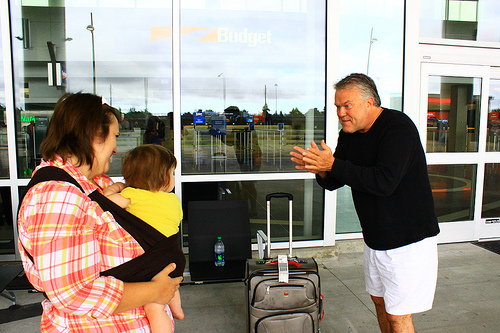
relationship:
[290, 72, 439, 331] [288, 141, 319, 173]
man h hand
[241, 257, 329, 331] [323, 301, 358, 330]
luggage on ground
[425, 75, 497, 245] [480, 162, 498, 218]
door with panel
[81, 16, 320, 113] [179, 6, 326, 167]
clouds in windows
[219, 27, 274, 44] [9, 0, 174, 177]
name on window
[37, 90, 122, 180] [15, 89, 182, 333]
head on mom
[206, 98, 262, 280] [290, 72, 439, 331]
reflection from man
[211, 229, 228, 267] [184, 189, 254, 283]
bottle on object